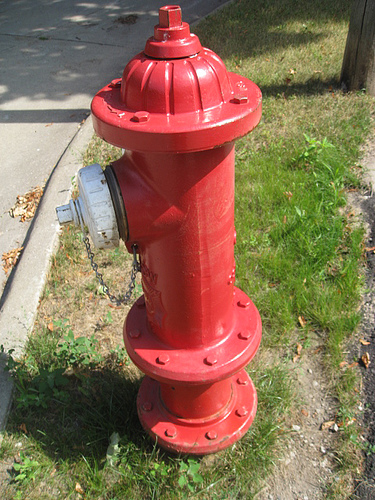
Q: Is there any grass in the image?
A: Yes, there is grass.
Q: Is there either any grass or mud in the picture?
A: Yes, there is grass.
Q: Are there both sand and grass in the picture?
A: No, there is grass but no sand.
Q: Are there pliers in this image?
A: No, there are no pliers.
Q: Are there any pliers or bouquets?
A: No, there are no pliers or bouquets.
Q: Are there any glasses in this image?
A: No, there are no glasses.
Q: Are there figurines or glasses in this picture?
A: No, there are no glasses or figurines.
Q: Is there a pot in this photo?
A: No, there are no pots.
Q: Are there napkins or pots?
A: No, there are no pots or napkins.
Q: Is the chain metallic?
A: Yes, the chain is metallic.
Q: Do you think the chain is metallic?
A: Yes, the chain is metallic.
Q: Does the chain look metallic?
A: Yes, the chain is metallic.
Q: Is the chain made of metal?
A: Yes, the chain is made of metal.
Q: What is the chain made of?
A: The chain is made of metal.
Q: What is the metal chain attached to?
A: The chain is attached to the cap.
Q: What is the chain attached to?
A: The chain is attached to the cap.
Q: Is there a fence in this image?
A: No, there are no fences.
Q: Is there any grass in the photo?
A: Yes, there is grass.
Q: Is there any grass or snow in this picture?
A: Yes, there is grass.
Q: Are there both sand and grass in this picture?
A: No, there is grass but no sand.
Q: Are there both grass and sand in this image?
A: No, there is grass but no sand.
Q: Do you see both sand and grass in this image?
A: No, there is grass but no sand.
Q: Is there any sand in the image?
A: No, there is no sand.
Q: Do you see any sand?
A: No, there is no sand.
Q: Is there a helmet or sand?
A: No, there are no sand or helmets.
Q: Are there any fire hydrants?
A: Yes, there is a fire hydrant.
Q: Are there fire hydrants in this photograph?
A: Yes, there is a fire hydrant.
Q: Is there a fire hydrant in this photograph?
A: Yes, there is a fire hydrant.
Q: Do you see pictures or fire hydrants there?
A: Yes, there is a fire hydrant.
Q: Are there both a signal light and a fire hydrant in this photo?
A: No, there is a fire hydrant but no traffic lights.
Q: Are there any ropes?
A: No, there are no ropes.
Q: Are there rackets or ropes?
A: No, there are no ropes or rackets.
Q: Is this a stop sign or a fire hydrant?
A: This is a fire hydrant.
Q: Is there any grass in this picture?
A: Yes, there is grass.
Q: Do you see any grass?
A: Yes, there is grass.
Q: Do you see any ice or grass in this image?
A: Yes, there is grass.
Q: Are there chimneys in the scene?
A: No, there are no chimneys.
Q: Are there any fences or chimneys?
A: No, there are no chimneys or fences.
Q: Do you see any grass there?
A: Yes, there is grass.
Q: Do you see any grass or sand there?
A: Yes, there is grass.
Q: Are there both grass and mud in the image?
A: No, there is grass but no mud.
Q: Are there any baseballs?
A: No, there are no baseballs.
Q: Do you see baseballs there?
A: No, there are no baseballs.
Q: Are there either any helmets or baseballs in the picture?
A: No, there are no baseballs or helmets.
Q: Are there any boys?
A: No, there are no boys.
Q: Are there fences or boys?
A: No, there are no boys or fences.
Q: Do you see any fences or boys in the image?
A: No, there are no boys or fences.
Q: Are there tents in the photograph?
A: No, there are no tents.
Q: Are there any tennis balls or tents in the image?
A: No, there are no tents or tennis balls.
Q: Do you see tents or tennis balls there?
A: No, there are no tents or tennis balls.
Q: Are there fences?
A: No, there are no fences.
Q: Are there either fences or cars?
A: No, there are no fences or cars.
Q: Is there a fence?
A: No, there are no fences.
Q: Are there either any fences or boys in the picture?
A: No, there are no fences or boys.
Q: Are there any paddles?
A: No, there are no paddles.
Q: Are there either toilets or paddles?
A: No, there are no paddles or toilets.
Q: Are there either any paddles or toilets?
A: No, there are no paddles or toilets.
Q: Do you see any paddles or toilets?
A: No, there are no paddles or toilets.